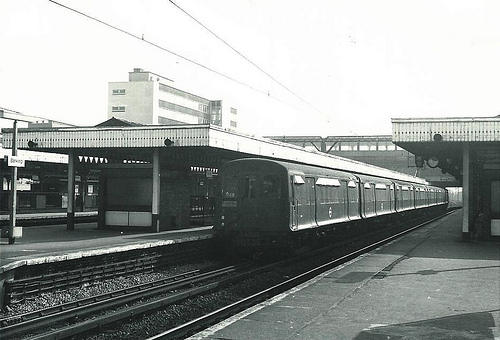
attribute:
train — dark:
[170, 123, 471, 289]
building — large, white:
[109, 68, 239, 133]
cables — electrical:
[192, 8, 239, 149]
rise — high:
[118, 62, 233, 139]